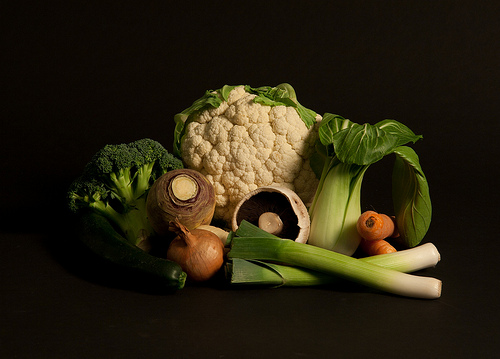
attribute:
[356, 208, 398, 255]
carrots — orange, chubby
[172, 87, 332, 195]
cauliflower — large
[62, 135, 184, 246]
broccoli — stalk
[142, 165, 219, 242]
rutabaga — upside down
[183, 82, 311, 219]
cauliflower — big 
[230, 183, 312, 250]
mushroom — big , on side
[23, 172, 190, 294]
cucumber — green, long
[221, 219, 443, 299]
vegetables — green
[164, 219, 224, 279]
onion — round, brown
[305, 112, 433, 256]
greens — leafy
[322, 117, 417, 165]
leaves — long